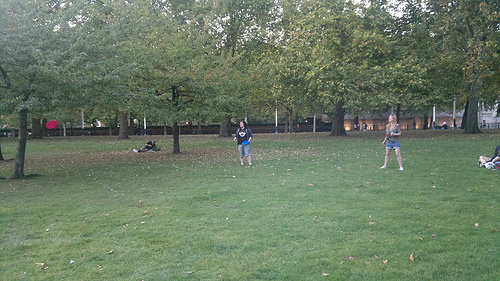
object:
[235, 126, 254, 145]
jacket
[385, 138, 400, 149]
jeans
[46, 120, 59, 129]
frisbee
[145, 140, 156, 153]
man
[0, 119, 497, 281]
park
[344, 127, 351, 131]
lights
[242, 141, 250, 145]
frisbee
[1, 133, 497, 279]
grass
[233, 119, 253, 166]
girl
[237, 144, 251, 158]
shorts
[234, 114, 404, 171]
people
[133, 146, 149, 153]
girls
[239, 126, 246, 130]
black top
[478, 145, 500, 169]
person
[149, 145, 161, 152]
belongings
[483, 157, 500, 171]
belongings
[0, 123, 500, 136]
fence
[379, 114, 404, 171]
girl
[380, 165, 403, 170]
shoes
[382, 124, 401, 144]
shirt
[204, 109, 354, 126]
air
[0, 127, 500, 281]
field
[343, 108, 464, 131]
building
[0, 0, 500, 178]
trees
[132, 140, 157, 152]
people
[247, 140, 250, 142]
hand